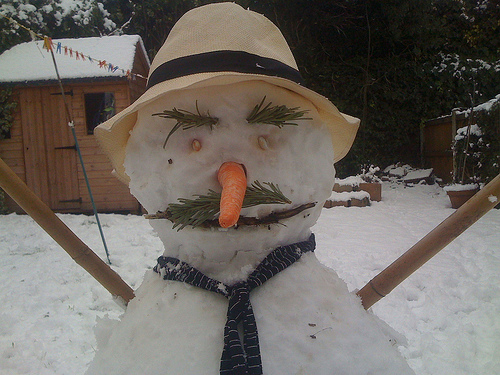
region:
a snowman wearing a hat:
[3, 5, 404, 371]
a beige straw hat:
[79, 5, 368, 180]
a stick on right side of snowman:
[360, 170, 495, 315]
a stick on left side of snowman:
[3, 155, 138, 316]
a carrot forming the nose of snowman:
[202, 156, 257, 231]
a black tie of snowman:
[138, 236, 328, 371]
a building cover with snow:
[5, 25, 150, 225]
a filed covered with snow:
[0, 202, 492, 367]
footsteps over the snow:
[402, 231, 497, 364]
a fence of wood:
[403, 96, 498, 204]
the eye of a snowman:
[185, 133, 206, 157]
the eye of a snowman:
[254, 127, 280, 152]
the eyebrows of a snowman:
[150, 104, 224, 136]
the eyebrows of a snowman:
[243, 97, 314, 132]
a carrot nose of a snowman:
[209, 160, 256, 227]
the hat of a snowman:
[91, 0, 379, 142]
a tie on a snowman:
[156, 239, 328, 370]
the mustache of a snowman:
[148, 184, 295, 216]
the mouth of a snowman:
[157, 205, 319, 231]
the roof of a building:
[38, 30, 136, 92]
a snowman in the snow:
[86, 0, 424, 368]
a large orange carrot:
[209, 155, 251, 229]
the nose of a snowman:
[211, 157, 258, 234]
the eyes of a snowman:
[182, 130, 279, 157]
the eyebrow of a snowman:
[243, 91, 314, 130]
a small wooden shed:
[4, 28, 159, 217]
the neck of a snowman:
[149, 235, 323, 287]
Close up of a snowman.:
[21, 2, 430, 372]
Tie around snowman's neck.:
[152, 230, 332, 373]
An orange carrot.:
[211, 154, 249, 239]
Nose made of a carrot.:
[208, 150, 251, 233]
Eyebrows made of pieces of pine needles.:
[155, 96, 309, 133]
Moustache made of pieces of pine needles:
[149, 183, 294, 223]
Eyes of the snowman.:
[183, 125, 274, 160]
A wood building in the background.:
[6, 33, 131, 223]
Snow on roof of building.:
[7, 15, 160, 82]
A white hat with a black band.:
[98, 1, 371, 159]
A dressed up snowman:
[2, 14, 495, 374]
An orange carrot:
[210, 161, 243, 224]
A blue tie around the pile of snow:
[157, 233, 317, 373]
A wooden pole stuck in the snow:
[352, 166, 498, 312]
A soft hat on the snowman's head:
[94, 4, 364, 149]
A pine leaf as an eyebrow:
[242, 97, 312, 130]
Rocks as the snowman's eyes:
[188, 132, 281, 155]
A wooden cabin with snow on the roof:
[0, 31, 167, 219]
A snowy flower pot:
[445, 180, 480, 210]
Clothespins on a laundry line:
[30, 34, 147, 90]